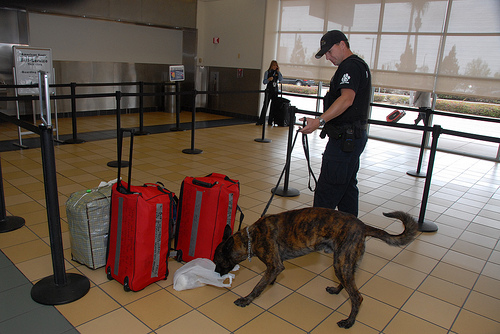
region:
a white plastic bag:
[170, 255, 238, 290]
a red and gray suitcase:
[172, 168, 245, 265]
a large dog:
[212, 203, 421, 328]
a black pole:
[30, 127, 97, 310]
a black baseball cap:
[310, 27, 349, 57]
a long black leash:
[257, 123, 321, 221]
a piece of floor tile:
[419, 275, 466, 307]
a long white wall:
[32, 12, 185, 64]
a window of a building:
[381, 35, 436, 74]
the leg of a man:
[320, 137, 365, 214]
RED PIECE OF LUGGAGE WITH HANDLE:
[100, 161, 169, 296]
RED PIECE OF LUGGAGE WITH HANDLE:
[163, 164, 253, 272]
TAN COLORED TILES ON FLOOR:
[13, 107, 485, 308]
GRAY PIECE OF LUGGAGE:
[63, 163, 145, 281]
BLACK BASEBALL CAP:
[296, 26, 341, 56]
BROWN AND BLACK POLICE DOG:
[206, 186, 398, 313]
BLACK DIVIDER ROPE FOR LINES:
[38, 63, 417, 230]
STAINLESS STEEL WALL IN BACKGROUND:
[6, 3, 256, 133]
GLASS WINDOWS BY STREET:
[267, 7, 492, 142]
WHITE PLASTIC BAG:
[157, 241, 229, 290]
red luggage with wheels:
[110, 169, 176, 293]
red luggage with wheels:
[173, 161, 241, 268]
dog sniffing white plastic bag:
[167, 216, 383, 321]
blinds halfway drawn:
[257, 0, 499, 110]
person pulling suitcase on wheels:
[381, 71, 443, 136]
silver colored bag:
[62, 172, 123, 279]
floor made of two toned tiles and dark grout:
[384, 254, 486, 326]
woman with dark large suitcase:
[254, 57, 299, 131]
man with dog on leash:
[211, 22, 413, 322]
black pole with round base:
[27, 121, 92, 308]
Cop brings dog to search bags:
[209, 26, 421, 327]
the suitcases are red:
[103, 169, 241, 291]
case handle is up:
[113, 125, 140, 199]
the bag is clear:
[66, 179, 123, 272]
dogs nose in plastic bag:
[168, 256, 240, 291]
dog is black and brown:
[176, 207, 419, 328]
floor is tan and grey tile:
[1, 106, 499, 331]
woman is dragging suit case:
[386, 82, 436, 127]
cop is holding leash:
[243, 118, 318, 264]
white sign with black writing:
[11, 42, 68, 148]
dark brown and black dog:
[206, 193, 361, 300]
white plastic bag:
[170, 256, 253, 304]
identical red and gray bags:
[123, 166, 253, 267]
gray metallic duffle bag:
[62, 188, 131, 300]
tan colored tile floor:
[408, 279, 446, 326]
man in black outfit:
[305, 35, 366, 193]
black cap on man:
[315, 27, 335, 47]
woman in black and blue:
[263, 55, 295, 147]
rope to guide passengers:
[13, 58, 236, 170]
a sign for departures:
[14, 43, 70, 113]